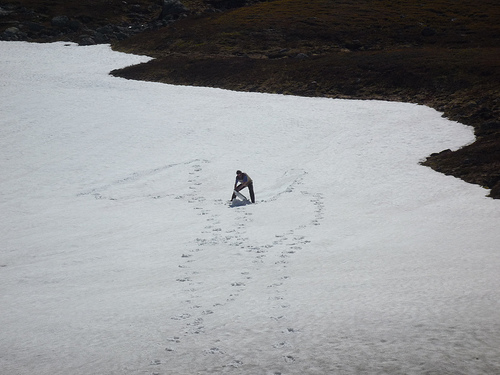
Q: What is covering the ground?
A: Snow.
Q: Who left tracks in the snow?
A: The man.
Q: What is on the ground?
A: Snow.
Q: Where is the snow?
A: On the ground.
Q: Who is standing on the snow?
A: A man.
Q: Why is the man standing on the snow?
A: Ice fishing.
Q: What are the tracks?
A: Footprints.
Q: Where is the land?
A: Behind the snow.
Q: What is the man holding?
A: A drill.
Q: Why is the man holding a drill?
A: To fish.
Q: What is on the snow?
A: Footprints.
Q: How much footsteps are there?
A: Plenty.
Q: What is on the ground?
A: Snow.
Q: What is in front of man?
A: Tracks.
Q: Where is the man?
A: Field.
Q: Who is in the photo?
A: A man.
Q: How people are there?
A: One.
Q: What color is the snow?
A: White.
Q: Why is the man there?
A: He is snowboarding.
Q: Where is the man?
A: On the mountain.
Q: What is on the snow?
A: Footprints.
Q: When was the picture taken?
A: During the day.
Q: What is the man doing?
A: Standing.